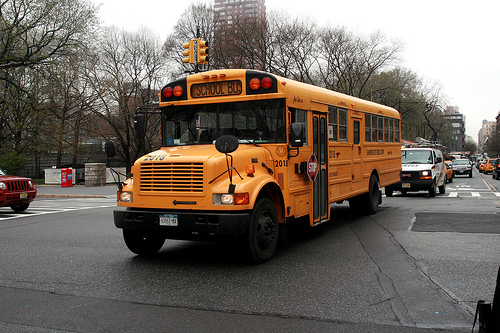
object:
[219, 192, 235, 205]
headlight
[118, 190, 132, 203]
headlight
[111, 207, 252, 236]
front bumper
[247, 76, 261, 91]
caution light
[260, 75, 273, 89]
caution light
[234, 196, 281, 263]
front tire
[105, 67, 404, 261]
bus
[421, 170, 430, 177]
headlight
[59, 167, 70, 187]
newspaper stand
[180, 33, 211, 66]
street light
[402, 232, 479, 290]
street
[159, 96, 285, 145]
windshield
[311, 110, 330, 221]
door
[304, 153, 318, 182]
stop sign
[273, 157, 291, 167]
number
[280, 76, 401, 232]
side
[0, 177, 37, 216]
front end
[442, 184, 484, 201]
pedestrian crossing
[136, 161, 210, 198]
grill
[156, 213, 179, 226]
license plate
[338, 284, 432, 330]
road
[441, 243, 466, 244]
road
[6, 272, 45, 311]
road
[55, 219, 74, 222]
road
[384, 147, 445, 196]
car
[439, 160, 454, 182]
car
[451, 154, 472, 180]
car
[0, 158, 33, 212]
car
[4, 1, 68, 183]
tree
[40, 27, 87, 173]
tree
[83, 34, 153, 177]
tree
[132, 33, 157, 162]
tree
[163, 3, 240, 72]
tree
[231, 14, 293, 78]
tree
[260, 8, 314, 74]
tree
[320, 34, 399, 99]
tree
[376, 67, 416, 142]
tree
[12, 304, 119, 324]
road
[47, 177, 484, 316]
intersection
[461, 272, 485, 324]
concrete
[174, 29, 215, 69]
stop light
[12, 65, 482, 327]
street